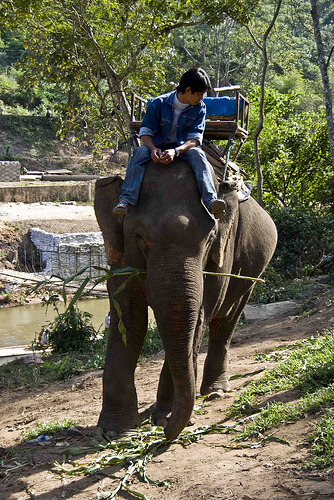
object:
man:
[111, 66, 226, 224]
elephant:
[92, 139, 278, 444]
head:
[123, 157, 219, 326]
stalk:
[114, 270, 267, 281]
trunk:
[144, 276, 204, 441]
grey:
[161, 276, 173, 305]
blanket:
[129, 91, 249, 142]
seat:
[129, 83, 250, 196]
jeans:
[119, 143, 218, 207]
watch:
[174, 148, 179, 160]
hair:
[178, 68, 214, 98]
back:
[200, 142, 243, 189]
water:
[0, 295, 154, 346]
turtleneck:
[172, 92, 191, 115]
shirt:
[139, 90, 208, 150]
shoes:
[209, 200, 228, 221]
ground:
[0, 282, 333, 500]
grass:
[224, 328, 333, 472]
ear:
[93, 174, 125, 268]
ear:
[210, 189, 240, 271]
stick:
[116, 270, 267, 284]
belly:
[202, 269, 244, 323]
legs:
[100, 277, 149, 414]